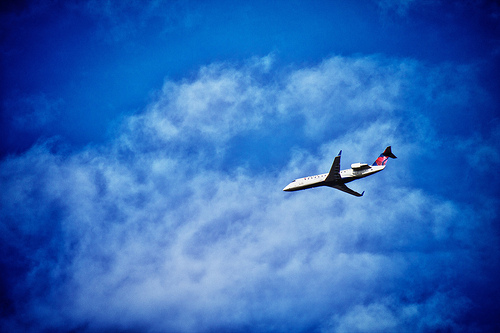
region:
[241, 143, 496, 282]
an airplane in the sky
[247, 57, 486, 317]
an airiplane in the air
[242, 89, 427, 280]
an airplane high in the sky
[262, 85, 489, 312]
an airplane high in the air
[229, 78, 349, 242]
a plane in the air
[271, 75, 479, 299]
a plane in the sky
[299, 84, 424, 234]
a plane flying high in the sky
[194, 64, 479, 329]
a plane flying high in the air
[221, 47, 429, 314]
a plane is high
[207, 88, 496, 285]
an airplane is high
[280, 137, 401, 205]
a plane in the sky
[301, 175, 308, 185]
a window on the plane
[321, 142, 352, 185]
a wing on the plane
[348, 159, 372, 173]
an engine on the plane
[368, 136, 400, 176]
the tail of a plane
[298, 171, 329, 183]
a row of windows on the plane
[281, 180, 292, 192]
the nose of a plane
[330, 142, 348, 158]
the tip of a plane wing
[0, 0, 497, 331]
a cloudy blue sky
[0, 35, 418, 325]
white clouds in the sky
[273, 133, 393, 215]
A lone plane in the sky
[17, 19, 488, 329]
An aerial shot of an aircraft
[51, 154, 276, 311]
Thin white clouds in the sky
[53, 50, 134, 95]
The clear blue sky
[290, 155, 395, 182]
A white airplane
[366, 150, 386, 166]
Red section of the plane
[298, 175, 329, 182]
Windows lining the plane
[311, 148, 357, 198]
The plane has two wings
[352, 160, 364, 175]
The plane's engine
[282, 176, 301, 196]
The white nosecone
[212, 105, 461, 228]
Plane in the sky.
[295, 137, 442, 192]
Wings on the plane.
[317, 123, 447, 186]
Red tail on the plane.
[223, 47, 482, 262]
White plane in the air.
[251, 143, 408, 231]
Windows on the plane.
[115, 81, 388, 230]
White clouds in the sky.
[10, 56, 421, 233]
Blue sky with white clouds.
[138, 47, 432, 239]
White clouds in a blue sky.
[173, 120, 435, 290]
Bright blue sky in the background.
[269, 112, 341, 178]
Plane flying in the air.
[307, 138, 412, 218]
white plane in air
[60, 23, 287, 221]
sky is bright blue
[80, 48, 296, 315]
thin clouds in sky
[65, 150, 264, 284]
white clouds are puffy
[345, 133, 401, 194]
plane has red tail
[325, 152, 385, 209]
plane has shadowed wings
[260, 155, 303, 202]
plane has white tip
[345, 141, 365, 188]
plane has white engines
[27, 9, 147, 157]
sky is clear and blue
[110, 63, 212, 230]
few clouds in sky